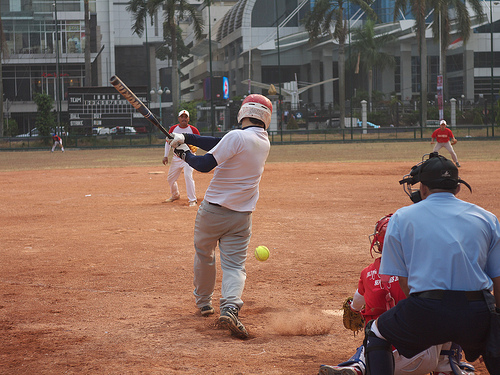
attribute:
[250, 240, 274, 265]
baseball — yellow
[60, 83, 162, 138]
scoreboard — black, white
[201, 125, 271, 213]
t shirt — white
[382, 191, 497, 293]
shirt — blue, short sleeve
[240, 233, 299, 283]
baseball — cleats, black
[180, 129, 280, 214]
white shirt — short sleeve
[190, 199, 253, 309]
pants — grey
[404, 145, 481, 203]
mask — black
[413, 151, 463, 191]
hat — black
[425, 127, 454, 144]
shirt — red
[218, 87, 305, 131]
cap — white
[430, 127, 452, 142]
shirt — red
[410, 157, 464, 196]
hat — black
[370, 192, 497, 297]
shirt — blue, short sleeve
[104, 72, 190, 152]
baseball jersey — red and white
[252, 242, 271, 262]
baseball — light green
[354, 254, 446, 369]
uniform — red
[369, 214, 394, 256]
mask — red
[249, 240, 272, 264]
softball — green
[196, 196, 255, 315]
pants — grey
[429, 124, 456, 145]
baseball jersey — bright, red